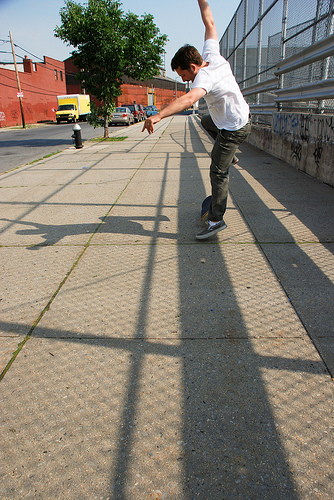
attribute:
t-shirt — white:
[152, 37, 257, 127]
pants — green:
[184, 112, 262, 219]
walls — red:
[17, 55, 100, 139]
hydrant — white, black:
[69, 121, 89, 151]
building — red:
[1, 50, 186, 127]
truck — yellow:
[52, 90, 97, 122]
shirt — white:
[190, 39, 250, 131]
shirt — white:
[186, 41, 248, 129]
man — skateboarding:
[142, 0, 259, 242]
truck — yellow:
[40, 79, 92, 135]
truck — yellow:
[56, 73, 113, 127]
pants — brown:
[196, 113, 253, 240]